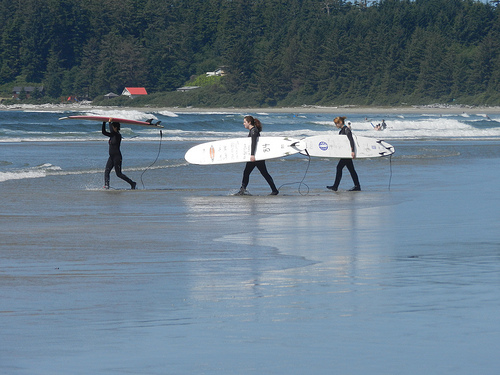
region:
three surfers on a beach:
[31, 80, 413, 274]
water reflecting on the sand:
[183, 305, 297, 355]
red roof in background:
[55, 37, 462, 256]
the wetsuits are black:
[22, 102, 416, 242]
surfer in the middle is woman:
[38, 90, 434, 230]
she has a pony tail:
[178, 107, 344, 203]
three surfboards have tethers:
[49, 92, 427, 224]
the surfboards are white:
[28, 102, 443, 247]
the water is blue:
[25, 135, 85, 165]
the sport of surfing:
[38, 95, 443, 242]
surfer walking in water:
[203, 111, 288, 203]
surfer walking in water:
[318, 107, 373, 217]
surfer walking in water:
[52, 96, 147, 200]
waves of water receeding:
[92, 191, 385, 318]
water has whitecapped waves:
[8, 119, 222, 189]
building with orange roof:
[107, 83, 149, 103]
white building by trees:
[121, 89, 141, 102]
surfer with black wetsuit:
[322, 111, 367, 199]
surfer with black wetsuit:
[225, 111, 286, 199]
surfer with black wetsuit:
[86, 117, 134, 204]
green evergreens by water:
[14, 12, 489, 105]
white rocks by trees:
[200, 63, 250, 75]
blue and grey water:
[2, 147, 252, 294]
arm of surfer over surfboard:
[244, 126, 271, 162]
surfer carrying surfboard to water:
[324, 119, 364, 192]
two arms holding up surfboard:
[88, 118, 150, 195]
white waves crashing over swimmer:
[356, 117, 478, 154]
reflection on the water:
[195, 193, 401, 303]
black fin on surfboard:
[370, 131, 395, 163]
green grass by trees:
[15, 77, 65, 121]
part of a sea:
[202, 277, 264, 317]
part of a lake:
[365, 312, 380, 327]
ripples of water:
[111, 241, 143, 271]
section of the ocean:
[68, 176, 101, 201]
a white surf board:
[212, 150, 219, 160]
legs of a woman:
[318, 180, 358, 198]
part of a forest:
[416, 39, 439, 59]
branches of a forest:
[282, 40, 312, 95]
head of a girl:
[250, 108, 257, 141]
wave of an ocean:
[43, 163, 55, 183]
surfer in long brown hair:
[218, 114, 280, 199]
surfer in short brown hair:
[316, 105, 379, 205]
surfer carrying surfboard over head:
[64, 103, 152, 193]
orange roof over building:
[111, 81, 143, 100]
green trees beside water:
[159, 18, 491, 114]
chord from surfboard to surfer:
[138, 124, 160, 184]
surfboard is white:
[188, 125, 295, 165]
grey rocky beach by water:
[211, 108, 496, 112]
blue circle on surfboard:
[311, 140, 333, 153]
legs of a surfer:
[318, 176, 365, 197]